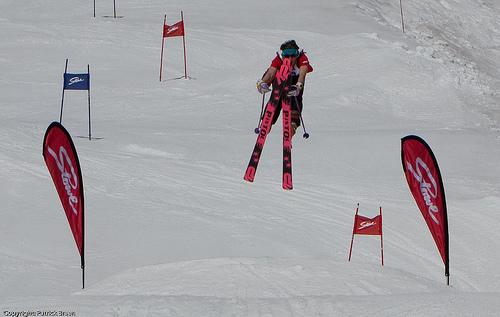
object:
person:
[252, 40, 313, 151]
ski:
[243, 64, 288, 182]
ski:
[281, 57, 294, 190]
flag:
[42, 121, 85, 290]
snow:
[0, 0, 499, 317]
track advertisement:
[59, 58, 91, 141]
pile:
[72, 255, 462, 299]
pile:
[446, 195, 499, 223]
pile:
[115, 142, 185, 159]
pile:
[359, 31, 460, 94]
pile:
[229, 26, 327, 48]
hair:
[280, 39, 301, 56]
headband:
[281, 48, 299, 55]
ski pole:
[290, 85, 310, 138]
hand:
[287, 84, 300, 99]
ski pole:
[254, 84, 268, 134]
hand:
[256, 81, 271, 94]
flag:
[159, 11, 188, 83]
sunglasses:
[281, 53, 299, 58]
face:
[281, 52, 298, 67]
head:
[281, 40, 300, 68]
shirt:
[269, 50, 313, 85]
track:
[184, 27, 273, 86]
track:
[75, 154, 126, 175]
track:
[69, 20, 163, 40]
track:
[235, 258, 293, 298]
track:
[0, 155, 54, 181]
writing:
[46, 144, 78, 215]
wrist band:
[295, 82, 304, 89]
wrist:
[296, 81, 303, 90]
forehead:
[281, 46, 298, 57]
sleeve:
[297, 52, 314, 73]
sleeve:
[270, 56, 282, 70]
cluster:
[416, 44, 435, 57]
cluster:
[456, 58, 466, 67]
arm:
[286, 53, 308, 98]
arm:
[257, 55, 281, 93]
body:
[273, 51, 304, 107]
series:
[60, 0, 384, 267]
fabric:
[43, 126, 83, 257]